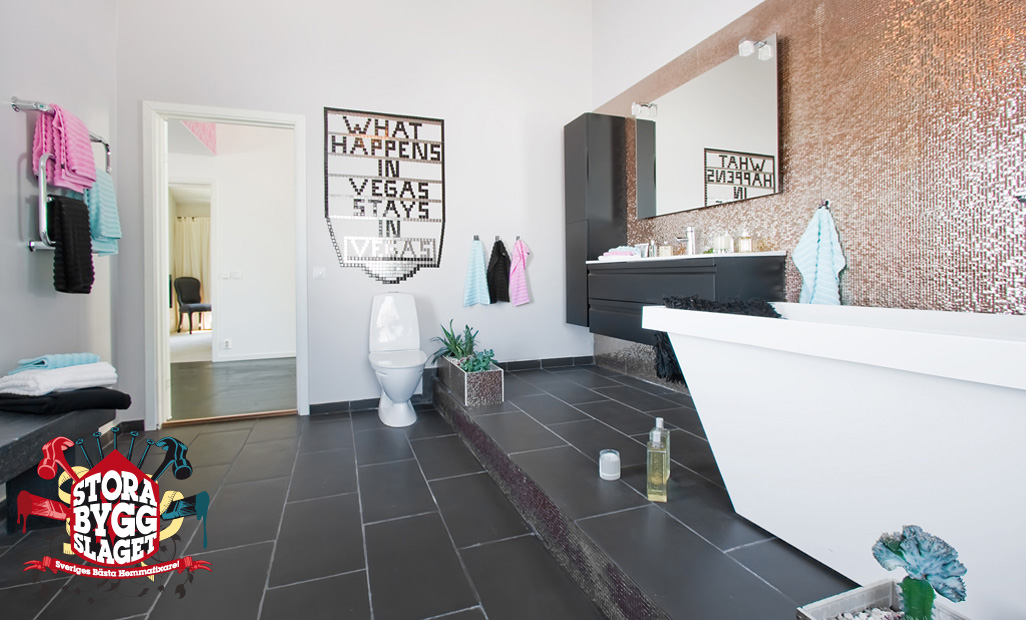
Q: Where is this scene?
A: In a bathroom.